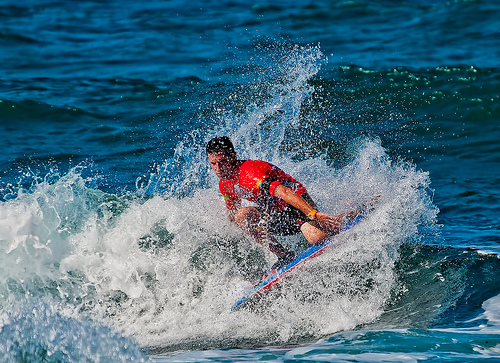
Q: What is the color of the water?
A: Blue.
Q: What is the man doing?
A: Wakeboarding.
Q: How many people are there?
A: One.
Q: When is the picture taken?
A: Daytime.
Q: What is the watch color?
A: Orange.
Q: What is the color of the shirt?
A: Red.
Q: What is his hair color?
A: Black.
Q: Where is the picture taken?
A: Ocean.